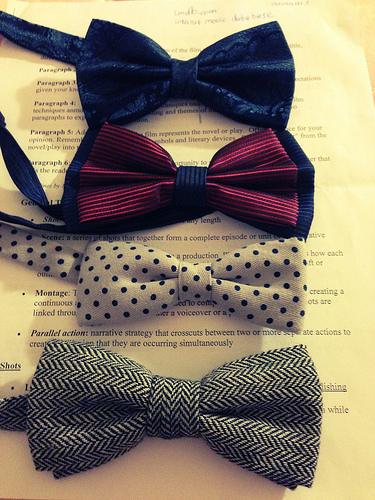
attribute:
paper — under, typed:
[5, 2, 373, 495]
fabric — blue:
[25, 22, 68, 57]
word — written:
[30, 327, 62, 336]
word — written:
[60, 328, 86, 336]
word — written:
[33, 287, 68, 297]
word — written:
[28, 128, 66, 135]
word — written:
[317, 153, 331, 162]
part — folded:
[316, 5, 373, 100]